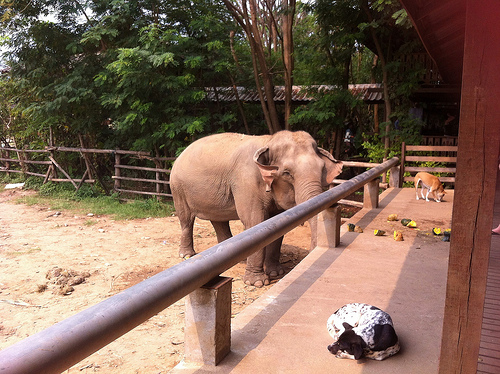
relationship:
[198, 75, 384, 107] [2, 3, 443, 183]
roof under trees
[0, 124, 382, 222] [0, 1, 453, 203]
fence in front of trees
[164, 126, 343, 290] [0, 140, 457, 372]
elephant in front of deck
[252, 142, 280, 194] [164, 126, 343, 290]
ear of elephant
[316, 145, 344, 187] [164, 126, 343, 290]
ear of elephant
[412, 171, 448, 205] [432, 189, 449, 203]
dog with head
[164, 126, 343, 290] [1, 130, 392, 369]
elephant in a pen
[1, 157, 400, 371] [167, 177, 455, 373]
pole along walkway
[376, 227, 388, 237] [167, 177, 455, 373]
fruit on walkway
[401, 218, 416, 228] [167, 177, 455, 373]
fruit on walkway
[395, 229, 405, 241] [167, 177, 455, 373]
fruit on walkway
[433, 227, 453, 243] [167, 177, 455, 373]
fruit on walkway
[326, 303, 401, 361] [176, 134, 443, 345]
dog sniffing ground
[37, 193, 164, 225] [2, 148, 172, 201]
grass next to fence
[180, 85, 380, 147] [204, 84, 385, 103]
building with roof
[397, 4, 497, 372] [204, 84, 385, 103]
building with roof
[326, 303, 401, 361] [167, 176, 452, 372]
dog curled up on porch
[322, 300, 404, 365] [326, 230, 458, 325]
dog sleeps on porch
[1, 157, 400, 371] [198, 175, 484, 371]
pole on deck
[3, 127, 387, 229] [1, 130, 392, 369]
fence along pen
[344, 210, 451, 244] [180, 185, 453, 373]
food on deck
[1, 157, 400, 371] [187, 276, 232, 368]
pole on pillars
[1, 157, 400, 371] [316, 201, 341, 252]
pole on pillars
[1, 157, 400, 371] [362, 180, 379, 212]
pole on pillars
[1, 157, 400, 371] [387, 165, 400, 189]
pole on pillars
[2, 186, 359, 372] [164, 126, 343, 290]
dirt under elephant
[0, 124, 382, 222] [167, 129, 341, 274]
fence behind elephant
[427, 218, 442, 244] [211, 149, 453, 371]
sliced fruit on deck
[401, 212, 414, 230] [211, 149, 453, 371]
sliced fruit on deck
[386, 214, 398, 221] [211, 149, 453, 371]
sliced fruit on deck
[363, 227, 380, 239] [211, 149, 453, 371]
sliced fruit on deck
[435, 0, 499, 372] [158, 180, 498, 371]
pillar on patio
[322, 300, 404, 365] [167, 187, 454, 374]
dog on patio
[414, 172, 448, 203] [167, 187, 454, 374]
dog on patio